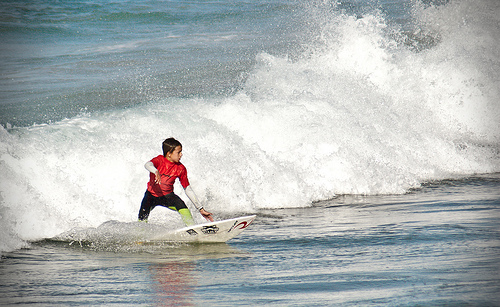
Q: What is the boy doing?
A: Surfing.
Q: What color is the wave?
A: White.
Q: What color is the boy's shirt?
A: Orange.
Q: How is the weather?
A: Sunny.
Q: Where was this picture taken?
A: An ocean.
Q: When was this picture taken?
A: Daytime.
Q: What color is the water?
A: Blue.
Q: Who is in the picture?
A: A boy.